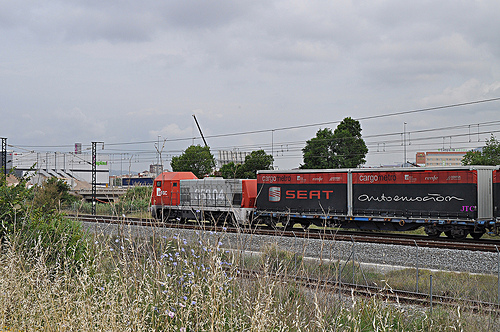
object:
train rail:
[216, 257, 495, 326]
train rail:
[66, 212, 498, 253]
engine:
[149, 171, 259, 225]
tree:
[463, 132, 497, 168]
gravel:
[75, 214, 500, 261]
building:
[108, 164, 176, 204]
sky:
[4, 7, 499, 169]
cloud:
[7, 4, 499, 140]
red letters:
[286, 190, 295, 198]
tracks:
[54, 207, 498, 252]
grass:
[36, 239, 378, 309]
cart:
[248, 169, 350, 218]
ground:
[8, 209, 498, 326]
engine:
[147, 171, 262, 221]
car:
[149, 171, 256, 222]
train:
[149, 164, 495, 239]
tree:
[302, 116, 368, 170]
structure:
[2, 149, 112, 225]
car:
[347, 166, 497, 233]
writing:
[357, 193, 463, 203]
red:
[149, 171, 184, 206]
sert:
[285, 190, 333, 199]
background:
[1, 4, 462, 234]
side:
[147, 173, 477, 214]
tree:
[217, 149, 276, 181]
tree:
[170, 144, 216, 174]